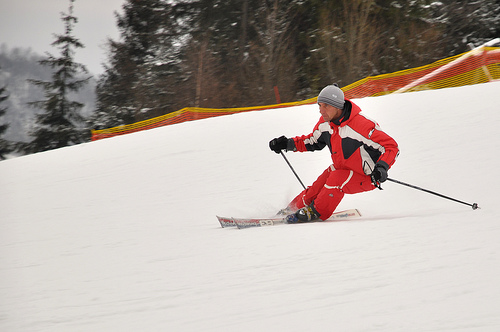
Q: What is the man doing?
A: Skiing.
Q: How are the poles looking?
A: Black.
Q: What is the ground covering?
A: Snow.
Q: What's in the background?
A: Trees.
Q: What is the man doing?
A: Skiing.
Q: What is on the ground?
A: Snow.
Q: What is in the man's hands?
A: Ski poles.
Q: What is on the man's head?
A: A hat.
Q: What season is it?
A: Winter.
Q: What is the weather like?
A: Cold.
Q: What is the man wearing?
A: A ski suit.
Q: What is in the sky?
A: Fog.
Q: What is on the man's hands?
A: Gloves.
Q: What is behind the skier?
A: Trees.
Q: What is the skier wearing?
A: Red, black and white clothing.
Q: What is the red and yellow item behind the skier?
A: A net.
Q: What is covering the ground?
A: Snow.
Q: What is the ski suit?
A: Red white and black.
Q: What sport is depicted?
A: Downhill skiing.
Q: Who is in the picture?
A: A man.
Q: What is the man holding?
A: Ski poles.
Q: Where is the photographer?
A: Ski slope.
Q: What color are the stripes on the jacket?
A: Black and white.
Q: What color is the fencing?
A: Yellow and red.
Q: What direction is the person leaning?
A: To his left.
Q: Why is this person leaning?
A: Balance.